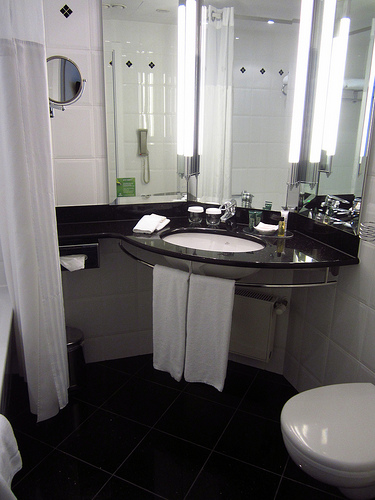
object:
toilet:
[279, 384, 374, 500]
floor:
[1, 353, 374, 499]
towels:
[151, 263, 237, 395]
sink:
[160, 228, 267, 280]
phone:
[137, 129, 151, 184]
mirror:
[101, 2, 375, 238]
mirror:
[46, 56, 88, 118]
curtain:
[1, 0, 70, 422]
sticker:
[116, 178, 136, 197]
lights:
[179, 0, 352, 190]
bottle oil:
[278, 216, 285, 237]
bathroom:
[1, 1, 372, 500]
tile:
[155, 391, 233, 448]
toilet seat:
[281, 383, 374, 473]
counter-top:
[54, 203, 361, 275]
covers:
[188, 206, 222, 215]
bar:
[116, 241, 340, 289]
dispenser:
[59, 242, 100, 271]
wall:
[44, 0, 112, 209]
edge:
[230, 278, 237, 320]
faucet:
[219, 200, 236, 223]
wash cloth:
[132, 211, 170, 236]